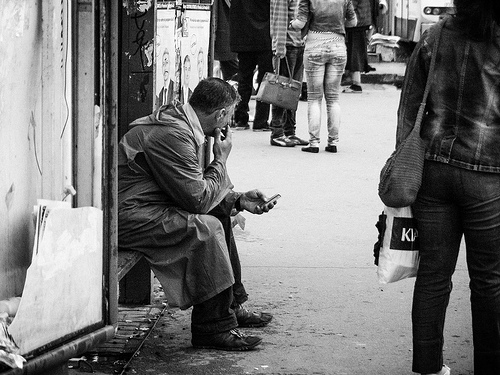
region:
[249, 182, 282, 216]
The man is holding a cell phone.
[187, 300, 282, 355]
The man's shoes are old.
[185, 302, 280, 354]
The man's shoes are black.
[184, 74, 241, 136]
The man has dark hair.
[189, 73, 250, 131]
The man has short hair.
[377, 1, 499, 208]
The woman is carrying a purse.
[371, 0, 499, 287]
The woman is carrying a bag.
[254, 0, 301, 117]
The person is carrying a bag.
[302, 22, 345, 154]
The person is wearing blue jeans.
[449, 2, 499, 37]
The woman has dark hair.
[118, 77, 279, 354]
A man is sitting.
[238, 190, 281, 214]
The man holds a phone.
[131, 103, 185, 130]
The jacket has a hood.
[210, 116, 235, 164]
The man's hand touches his face.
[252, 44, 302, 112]
A person holds a handbag.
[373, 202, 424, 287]
A person carries a shopping bag.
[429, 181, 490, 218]
The pants are black.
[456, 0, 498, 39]
The woman has dark hair.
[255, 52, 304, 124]
bag in woman's hand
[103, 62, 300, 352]
man sitting on a stoop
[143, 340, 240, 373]
shadow on the ground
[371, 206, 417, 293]
plastic bag in woman's hand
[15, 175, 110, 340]
broken area of a truck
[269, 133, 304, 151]
sneakers on a woman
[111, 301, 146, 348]
brick floor in a street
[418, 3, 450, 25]
sign above a road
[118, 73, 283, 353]
Man sitting with long coat on and hand to his face.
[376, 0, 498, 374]
Lady walking with purse on shoulder and shopping bag in her hand.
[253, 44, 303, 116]
A persons hand cluthing handels of a large purse.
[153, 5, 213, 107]
Poster on a wall showing male faces on it.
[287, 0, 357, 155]
A person standing back toward us with faded spots on pants.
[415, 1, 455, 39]
Lights on a vehicle in the background.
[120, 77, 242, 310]
Man sitting wearing a long rain coat.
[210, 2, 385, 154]
Five people standing in the distance.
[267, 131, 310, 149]
Pair of black and white sneakers with laces.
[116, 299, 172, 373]
Cigarette butts littering the ground.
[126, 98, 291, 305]
man holding a phone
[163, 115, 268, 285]
a man wearing a coat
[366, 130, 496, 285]
a person holding a bag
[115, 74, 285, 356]
man holding a phone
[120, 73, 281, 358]
man sitting on a truck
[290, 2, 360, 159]
a girl wearing tight jeans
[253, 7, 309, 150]
a man holding a bag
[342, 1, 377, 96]
a woman wearing a black skirt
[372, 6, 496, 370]
a woman with a shoulder bag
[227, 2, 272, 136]
man wearing black clothes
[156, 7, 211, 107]
poster on a truck door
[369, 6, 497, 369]
woman carrying a plastic bag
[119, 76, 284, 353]
man sitting with his hand to his face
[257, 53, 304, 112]
handbag woman is carrying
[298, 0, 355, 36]
black top woman is wearing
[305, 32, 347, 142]
tight blue jeans woman is wearing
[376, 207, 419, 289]
black and white bag woman is carrying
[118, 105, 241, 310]
coat man is wearing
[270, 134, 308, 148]
black and white tennis shoes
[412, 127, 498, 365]
black pants woman is wearing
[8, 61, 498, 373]
sidewalk people are on